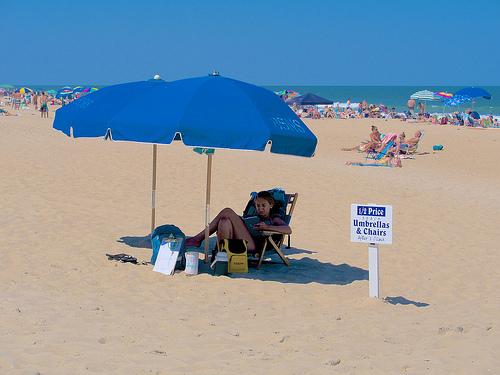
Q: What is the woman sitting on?
A: A chair.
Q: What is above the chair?
A: An umbrella.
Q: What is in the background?
A: Other beaches.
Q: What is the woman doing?
A: Reading.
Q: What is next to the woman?
A: A white sign.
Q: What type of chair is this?
A: A beach chair.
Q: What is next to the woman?
A: A yellow bag.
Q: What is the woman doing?
A: Selling umbrellas and chairs.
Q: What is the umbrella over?
A: The woman.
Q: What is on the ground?
A: Brown sand.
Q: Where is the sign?
A: In the sand.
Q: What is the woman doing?
A: Reading.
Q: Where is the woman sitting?
A: On a chair.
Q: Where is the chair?
A: On the sand.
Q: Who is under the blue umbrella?
A: A lady.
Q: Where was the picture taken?
A: Beach.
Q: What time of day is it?
A: Day time.